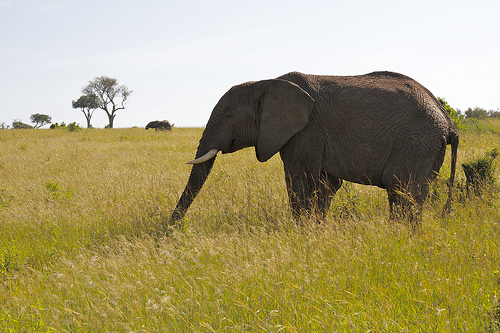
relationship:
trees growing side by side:
[69, 77, 130, 128] [72, 75, 133, 164]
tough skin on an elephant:
[314, 93, 420, 223] [172, 50, 491, 225]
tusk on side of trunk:
[182, 148, 219, 165] [168, 131, 219, 226]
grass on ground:
[134, 206, 494, 302] [2, 244, 498, 333]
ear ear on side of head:
[256, 79, 316, 162] [211, 85, 308, 167]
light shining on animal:
[6, 70, 190, 168] [168, 70, 458, 234]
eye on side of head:
[223, 110, 231, 120] [161, 74, 319, 237]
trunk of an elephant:
[168, 131, 219, 226] [138, 52, 494, 284]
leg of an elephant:
[283, 168, 325, 233] [301, 162, 341, 265]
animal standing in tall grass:
[168, 70, 458, 234] [345, 185, 477, 290]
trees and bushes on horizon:
[58, 77, 144, 134] [12, 70, 183, 222]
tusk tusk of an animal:
[182, 148, 219, 165] [168, 70, 458, 234]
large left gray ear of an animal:
[261, 112, 304, 192] [168, 70, 458, 234]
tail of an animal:
[445, 133, 460, 219] [168, 70, 458, 234]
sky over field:
[3, 53, 498, 133] [63, 121, 158, 285]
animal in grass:
[136, 100, 178, 130] [2, 121, 497, 328]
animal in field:
[168, 70, 458, 234] [11, 117, 498, 330]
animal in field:
[168, 70, 458, 234] [46, 70, 427, 267]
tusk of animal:
[182, 148, 219, 165] [168, 70, 458, 234]